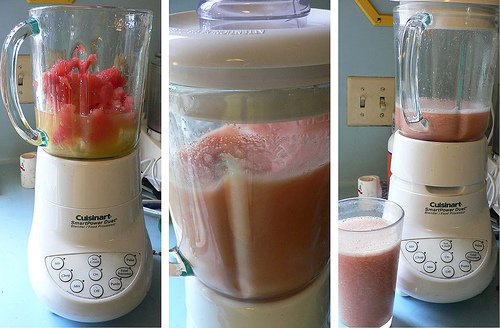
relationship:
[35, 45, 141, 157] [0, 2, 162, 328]
fruit inside blender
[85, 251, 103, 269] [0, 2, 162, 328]
button on top of blender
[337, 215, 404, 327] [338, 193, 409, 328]
shake inside glass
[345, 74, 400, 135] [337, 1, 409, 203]
outlet mounted on wall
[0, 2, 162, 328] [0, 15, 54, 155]
blender has handle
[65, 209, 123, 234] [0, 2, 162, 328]
name painted on blender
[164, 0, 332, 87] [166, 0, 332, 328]
cover on blender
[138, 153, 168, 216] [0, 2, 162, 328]
cord near blender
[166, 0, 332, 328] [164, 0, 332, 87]
blender has cover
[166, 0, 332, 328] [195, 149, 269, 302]
blender has groove